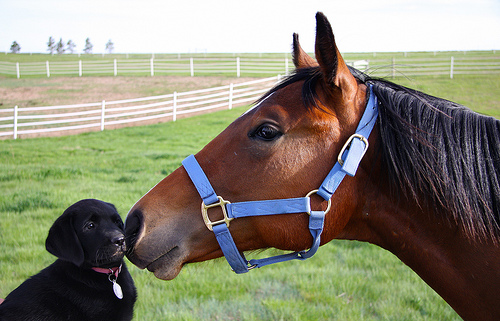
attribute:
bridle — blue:
[222, 190, 326, 264]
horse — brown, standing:
[121, 1, 479, 285]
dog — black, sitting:
[1, 165, 123, 313]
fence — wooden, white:
[55, 96, 92, 132]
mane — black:
[387, 82, 500, 219]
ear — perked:
[308, 7, 346, 94]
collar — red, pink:
[88, 264, 128, 283]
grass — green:
[91, 130, 106, 154]